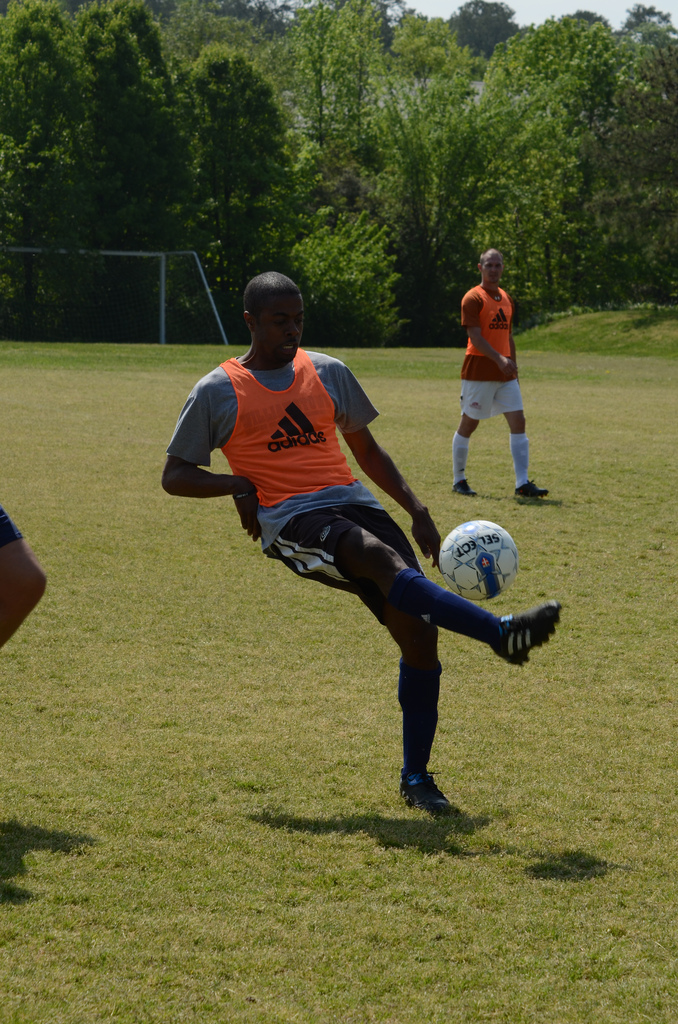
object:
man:
[452, 247, 551, 496]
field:
[45, 236, 600, 871]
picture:
[0, 0, 673, 1024]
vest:
[466, 285, 513, 356]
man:
[159, 271, 562, 815]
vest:
[219, 348, 359, 506]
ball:
[439, 518, 519, 598]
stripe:
[439, 520, 520, 600]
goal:
[0, 238, 241, 369]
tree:
[0, 0, 240, 351]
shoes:
[396, 597, 562, 818]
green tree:
[525, 11, 631, 120]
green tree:
[572, 5, 676, 296]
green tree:
[175, 39, 306, 271]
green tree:
[1, 0, 123, 340]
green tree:
[440, 11, 585, 323]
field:
[0, 336, 174, 541]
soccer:
[0, 0, 676, 1021]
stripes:
[508, 629, 531, 656]